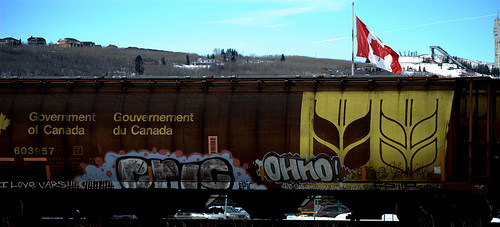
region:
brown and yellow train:
[0, 71, 499, 214]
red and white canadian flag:
[347, 1, 404, 78]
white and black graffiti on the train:
[64, 145, 344, 201]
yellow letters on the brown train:
[23, 103, 196, 139]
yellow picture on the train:
[295, 85, 457, 191]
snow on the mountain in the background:
[394, 50, 468, 77]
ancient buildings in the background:
[1, 32, 111, 50]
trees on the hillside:
[127, 43, 292, 78]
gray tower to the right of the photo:
[489, 8, 499, 72]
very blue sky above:
[1, 0, 497, 55]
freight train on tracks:
[2, 59, 498, 220]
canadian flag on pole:
[339, 0, 409, 82]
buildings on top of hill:
[2, 30, 114, 52]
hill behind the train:
[0, 45, 130, 77]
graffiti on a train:
[106, 147, 245, 195]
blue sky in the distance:
[11, 2, 212, 33]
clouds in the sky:
[251, 6, 323, 19]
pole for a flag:
[342, 1, 363, 81]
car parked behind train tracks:
[199, 203, 244, 225]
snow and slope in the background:
[402, 41, 494, 78]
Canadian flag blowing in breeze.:
[349, 4, 411, 77]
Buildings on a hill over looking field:
[1, 23, 115, 58]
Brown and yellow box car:
[5, 67, 496, 192]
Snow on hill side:
[389, 42, 466, 82]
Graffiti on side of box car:
[76, 138, 356, 198]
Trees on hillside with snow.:
[124, 42, 312, 79]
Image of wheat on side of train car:
[291, 70, 466, 200]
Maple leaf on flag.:
[350, 6, 412, 72]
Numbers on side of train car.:
[5, 136, 74, 161]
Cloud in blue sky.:
[217, 5, 327, 48]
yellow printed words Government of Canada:
[21, 109, 100, 139]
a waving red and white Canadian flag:
[349, 4, 409, 79]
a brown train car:
[1, 71, 494, 218]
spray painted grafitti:
[255, 149, 335, 190]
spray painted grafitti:
[92, 147, 242, 198]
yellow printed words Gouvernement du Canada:
[109, 109, 203, 141]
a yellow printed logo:
[296, 89, 450, 184]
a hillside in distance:
[5, 37, 375, 79]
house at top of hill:
[25, 34, 45, 47]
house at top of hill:
[55, 37, 82, 48]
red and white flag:
[345, 3, 402, 71]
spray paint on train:
[111, 148, 336, 195]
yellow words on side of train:
[107, 104, 201, 146]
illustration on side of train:
[303, 91, 447, 176]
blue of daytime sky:
[54, 4, 135, 33]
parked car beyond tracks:
[209, 197, 249, 224]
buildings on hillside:
[11, 33, 103, 53]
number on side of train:
[5, 144, 62, 161]